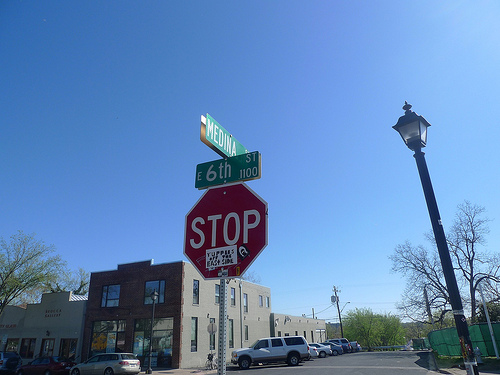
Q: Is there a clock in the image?
A: No, there are no clocks.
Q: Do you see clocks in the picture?
A: No, there are no clocks.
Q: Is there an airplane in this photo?
A: No, there are no airplanes.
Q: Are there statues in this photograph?
A: No, there are no statues.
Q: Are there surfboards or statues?
A: No, there are no statues or surfboards.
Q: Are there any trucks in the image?
A: Yes, there is a truck.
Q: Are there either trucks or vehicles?
A: Yes, there is a truck.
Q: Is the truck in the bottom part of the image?
A: Yes, the truck is in the bottom of the image.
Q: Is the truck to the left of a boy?
A: No, the truck is to the left of a vehicle.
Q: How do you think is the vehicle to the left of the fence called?
A: The vehicle is a truck.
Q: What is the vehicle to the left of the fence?
A: The vehicle is a truck.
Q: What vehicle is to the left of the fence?
A: The vehicle is a truck.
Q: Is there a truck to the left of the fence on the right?
A: Yes, there is a truck to the left of the fence.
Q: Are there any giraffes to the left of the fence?
A: No, there is a truck to the left of the fence.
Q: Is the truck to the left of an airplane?
A: No, the truck is to the left of the fence.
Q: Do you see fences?
A: Yes, there is a fence.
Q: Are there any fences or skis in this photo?
A: Yes, there is a fence.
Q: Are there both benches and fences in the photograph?
A: No, there is a fence but no benches.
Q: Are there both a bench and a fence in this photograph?
A: No, there is a fence but no benches.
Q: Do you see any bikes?
A: No, there are no bikes.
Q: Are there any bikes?
A: No, there are no bikes.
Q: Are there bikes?
A: No, there are no bikes.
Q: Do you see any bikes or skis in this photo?
A: No, there are no bikes or skis.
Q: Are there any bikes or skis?
A: No, there are no bikes or skis.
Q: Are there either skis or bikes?
A: No, there are no bikes or skis.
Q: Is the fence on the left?
A: No, the fence is on the right of the image.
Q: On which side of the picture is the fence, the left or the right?
A: The fence is on the right of the image.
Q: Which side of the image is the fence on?
A: The fence is on the right of the image.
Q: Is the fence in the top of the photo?
A: No, the fence is in the bottom of the image.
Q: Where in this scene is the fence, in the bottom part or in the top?
A: The fence is in the bottom of the image.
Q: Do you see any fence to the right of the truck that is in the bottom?
A: Yes, there is a fence to the right of the truck.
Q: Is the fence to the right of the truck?
A: Yes, the fence is to the right of the truck.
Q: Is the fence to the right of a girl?
A: No, the fence is to the right of the truck.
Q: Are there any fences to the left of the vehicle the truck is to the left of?
A: No, the fence is to the right of the vehicle.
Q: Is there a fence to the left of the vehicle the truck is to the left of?
A: No, the fence is to the right of the vehicle.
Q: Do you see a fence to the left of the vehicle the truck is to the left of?
A: No, the fence is to the right of the vehicle.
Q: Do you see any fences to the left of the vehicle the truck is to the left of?
A: No, the fence is to the right of the vehicle.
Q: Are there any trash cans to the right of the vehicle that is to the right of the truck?
A: No, there is a fence to the right of the vehicle.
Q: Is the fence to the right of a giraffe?
A: No, the fence is to the right of a vehicle.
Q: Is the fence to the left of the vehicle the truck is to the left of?
A: No, the fence is to the right of the vehicle.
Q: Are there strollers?
A: No, there are no strollers.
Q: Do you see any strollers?
A: No, there are no strollers.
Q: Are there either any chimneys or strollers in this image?
A: No, there are no strollers or chimneys.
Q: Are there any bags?
A: No, there are no bags.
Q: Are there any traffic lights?
A: No, there are no traffic lights.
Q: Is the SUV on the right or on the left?
A: The SUV is on the left of the image.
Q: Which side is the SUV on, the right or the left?
A: The SUV is on the left of the image.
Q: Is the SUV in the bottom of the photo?
A: Yes, the SUV is in the bottom of the image.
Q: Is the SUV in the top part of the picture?
A: No, the SUV is in the bottom of the image.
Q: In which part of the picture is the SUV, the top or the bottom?
A: The SUV is in the bottom of the image.